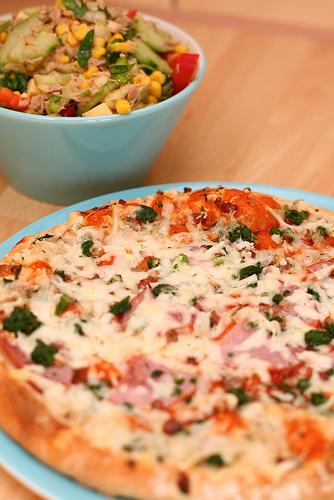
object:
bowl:
[0, 8, 204, 207]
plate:
[0, 180, 334, 500]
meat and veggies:
[5, 4, 178, 98]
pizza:
[0, 185, 334, 500]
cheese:
[129, 273, 226, 347]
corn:
[51, 19, 89, 49]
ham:
[123, 352, 181, 402]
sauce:
[227, 191, 280, 249]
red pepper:
[171, 50, 197, 92]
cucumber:
[2, 17, 57, 60]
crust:
[21, 389, 90, 472]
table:
[220, 3, 330, 156]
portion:
[88, 203, 246, 268]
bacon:
[244, 336, 299, 389]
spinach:
[225, 221, 261, 251]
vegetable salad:
[59, 26, 153, 107]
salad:
[28, 56, 126, 108]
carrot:
[147, 20, 174, 54]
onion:
[89, 75, 135, 104]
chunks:
[213, 309, 286, 404]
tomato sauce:
[246, 197, 264, 233]